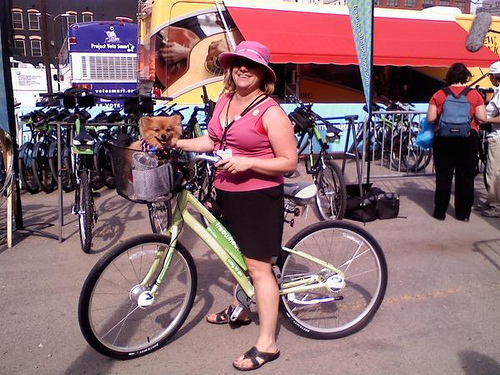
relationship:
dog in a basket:
[120, 114, 188, 170] [102, 128, 182, 208]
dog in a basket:
[124, 114, 184, 178] [100, 132, 179, 202]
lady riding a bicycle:
[177, 41, 299, 372] [69, 154, 392, 362]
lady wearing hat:
[177, 41, 299, 372] [216, 42, 278, 84]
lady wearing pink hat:
[177, 41, 299, 372] [217, 40, 277, 82]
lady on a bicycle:
[177, 41, 299, 372] [76, 140, 389, 361]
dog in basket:
[124, 114, 184, 178] [102, 128, 182, 208]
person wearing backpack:
[431, 57, 476, 149] [440, 110, 474, 143]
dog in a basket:
[124, 114, 184, 178] [106, 132, 176, 199]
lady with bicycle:
[177, 38, 299, 371] [69, 154, 392, 362]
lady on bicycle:
[177, 41, 299, 372] [69, 154, 392, 362]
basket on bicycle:
[102, 139, 210, 209] [69, 154, 392, 362]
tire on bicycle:
[72, 229, 202, 365] [76, 140, 389, 361]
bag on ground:
[346, 181, 409, 226] [396, 230, 484, 301]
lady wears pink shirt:
[177, 41, 299, 372] [208, 87, 293, 197]